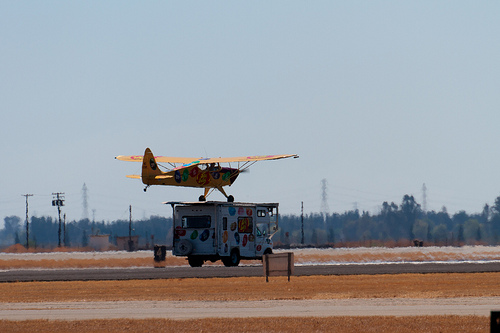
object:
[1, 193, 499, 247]
trees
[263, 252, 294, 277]
sign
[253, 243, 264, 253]
colorful stickers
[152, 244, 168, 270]
garbage can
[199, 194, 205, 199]
wheel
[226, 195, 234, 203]
wheel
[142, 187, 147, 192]
wheel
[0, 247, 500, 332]
ground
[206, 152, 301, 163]
wings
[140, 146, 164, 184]
tail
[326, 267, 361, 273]
asphalt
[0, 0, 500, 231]
sky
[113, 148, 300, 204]
plane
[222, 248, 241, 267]
wheel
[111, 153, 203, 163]
wings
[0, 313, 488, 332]
grass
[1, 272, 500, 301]
grass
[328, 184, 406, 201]
power lines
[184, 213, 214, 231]
window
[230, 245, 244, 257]
stickers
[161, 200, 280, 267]
truck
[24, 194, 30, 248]
pole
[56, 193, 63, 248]
pole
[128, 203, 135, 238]
pole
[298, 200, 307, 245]
pole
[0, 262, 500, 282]
road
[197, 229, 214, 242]
drawings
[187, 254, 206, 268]
wheel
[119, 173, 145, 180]
wings